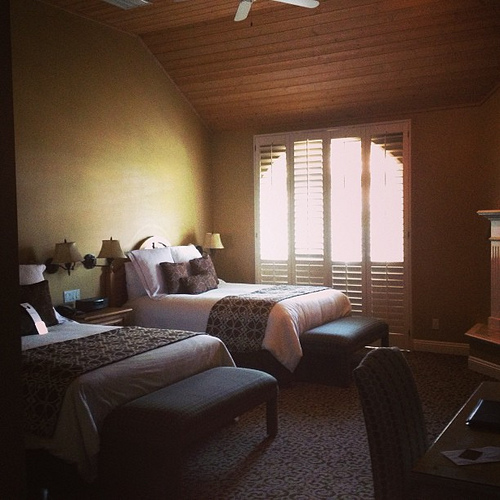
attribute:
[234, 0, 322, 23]
fan — white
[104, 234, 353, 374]
bed — matching, made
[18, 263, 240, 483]
bed — made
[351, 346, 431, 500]
chair — brown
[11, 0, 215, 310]
wall — yellow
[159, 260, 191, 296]
pillow — decorative, brown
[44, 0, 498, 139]
ceiling — wooden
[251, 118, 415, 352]
shade — white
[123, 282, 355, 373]
sheet — white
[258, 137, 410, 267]
window — sunlit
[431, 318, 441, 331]
outlet — white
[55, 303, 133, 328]
table — wooden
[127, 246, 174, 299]
pillow — white